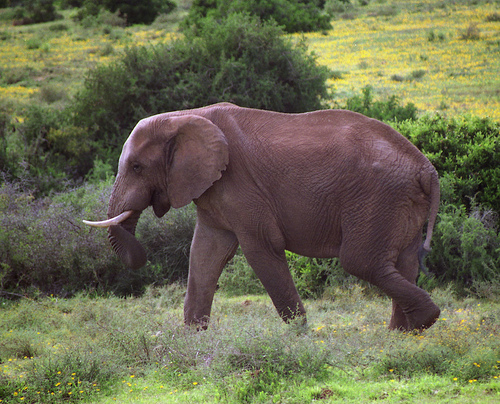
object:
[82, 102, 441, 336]
elephant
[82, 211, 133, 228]
tusk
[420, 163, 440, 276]
tail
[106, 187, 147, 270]
trunk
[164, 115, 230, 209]
ear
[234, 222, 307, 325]
leg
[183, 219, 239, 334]
leg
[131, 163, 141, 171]
eye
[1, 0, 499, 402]
grass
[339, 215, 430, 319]
leg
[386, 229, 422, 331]
leg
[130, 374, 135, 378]
flower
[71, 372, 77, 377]
flower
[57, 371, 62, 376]
flower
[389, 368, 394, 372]
flower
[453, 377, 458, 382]
flower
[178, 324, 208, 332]
foot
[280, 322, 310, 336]
foot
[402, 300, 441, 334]
foot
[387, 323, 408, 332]
foot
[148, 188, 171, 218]
mouth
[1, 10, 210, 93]
bush